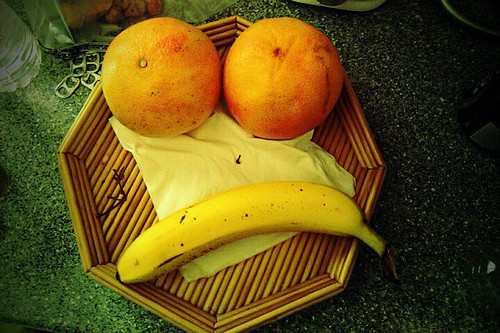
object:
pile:
[53, 51, 102, 99]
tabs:
[51, 49, 100, 99]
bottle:
[0, 2, 41, 93]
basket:
[56, 15, 384, 333]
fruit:
[100, 16, 222, 138]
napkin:
[106, 115, 356, 282]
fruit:
[221, 16, 343, 140]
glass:
[0, 50, 37, 67]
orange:
[221, 16, 342, 140]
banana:
[115, 180, 381, 284]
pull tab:
[55, 75, 80, 99]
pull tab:
[85, 51, 100, 73]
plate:
[55, 15, 383, 333]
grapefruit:
[221, 16, 341, 140]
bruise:
[315, 55, 332, 115]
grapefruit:
[101, 17, 222, 137]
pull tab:
[70, 54, 87, 77]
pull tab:
[81, 71, 101, 90]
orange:
[100, 16, 221, 137]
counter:
[2, 0, 500, 333]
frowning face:
[56, 16, 387, 333]